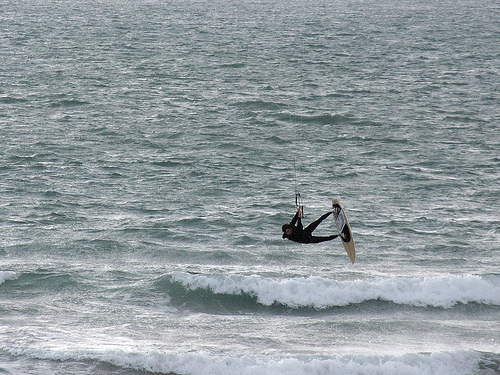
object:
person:
[281, 206, 348, 243]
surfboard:
[331, 198, 357, 265]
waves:
[0, 312, 498, 375]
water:
[0, 0, 499, 375]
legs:
[308, 234, 341, 243]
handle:
[294, 190, 306, 220]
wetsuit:
[284, 210, 337, 245]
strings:
[292, 117, 298, 207]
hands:
[298, 210, 302, 219]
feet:
[331, 207, 340, 213]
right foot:
[339, 231, 348, 240]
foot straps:
[339, 232, 346, 243]